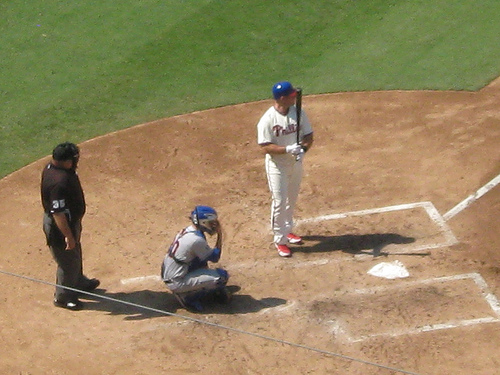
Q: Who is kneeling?
A: Catcher.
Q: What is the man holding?
A: Batter.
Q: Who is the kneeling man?
A: Catcher.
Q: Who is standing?
A: Umpire.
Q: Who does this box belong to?
A: The batter.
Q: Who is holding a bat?
A: A man.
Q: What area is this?
A: Baseball field.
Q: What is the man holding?
A: A bat.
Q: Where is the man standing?
A: Baseball field.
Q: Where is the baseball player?
A: At the plate.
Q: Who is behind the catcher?
A: The umpire.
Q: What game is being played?
A: Baseball.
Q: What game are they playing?
A: Baseball.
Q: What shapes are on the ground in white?
A: Rectangles.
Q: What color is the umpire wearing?
A: Black.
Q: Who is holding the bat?
A: The man.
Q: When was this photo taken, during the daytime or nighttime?
A: Daytime.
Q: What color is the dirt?
A: Brown.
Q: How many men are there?
A: Three.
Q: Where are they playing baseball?
A: Baseball field.